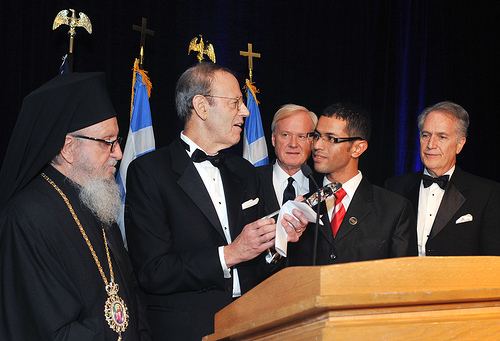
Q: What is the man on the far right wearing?
A: A suit and bow tie.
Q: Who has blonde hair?
A: The man in a suit.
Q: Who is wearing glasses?
A: The man in a suit.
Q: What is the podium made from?
A: Wood.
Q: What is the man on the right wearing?
A: A suit.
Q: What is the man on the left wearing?
A: A large gold necklace.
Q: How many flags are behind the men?
A: Four.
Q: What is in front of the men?
A: A podium.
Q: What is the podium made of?
A: Wood.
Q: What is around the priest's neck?
A: Large gold necklace.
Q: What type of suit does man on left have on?
A: Tuxedo.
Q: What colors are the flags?
A: Blue and white.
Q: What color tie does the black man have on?
A: Red.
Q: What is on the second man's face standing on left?
A: Glasses.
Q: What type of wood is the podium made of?
A: Oak.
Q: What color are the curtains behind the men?
A: Black.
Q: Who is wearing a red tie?
A: Young black man.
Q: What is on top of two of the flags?
A: Eagles.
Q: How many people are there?
A: 5.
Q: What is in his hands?
A: Award.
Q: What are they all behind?
A: Podium.